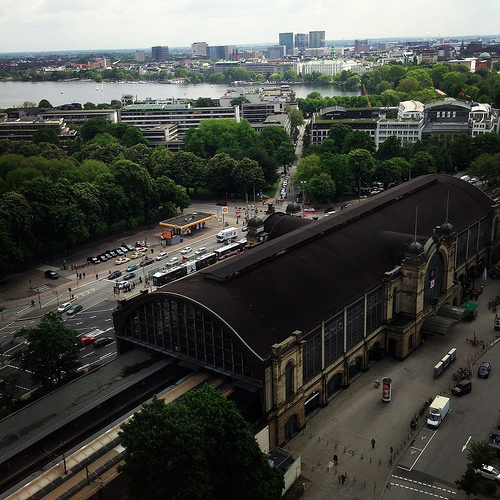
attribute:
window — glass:
[198, 351, 211, 372]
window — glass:
[132, 312, 141, 324]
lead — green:
[133, 167, 135, 170]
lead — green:
[102, 181, 104, 183]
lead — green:
[90, 167, 95, 172]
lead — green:
[220, 162, 222, 165]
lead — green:
[243, 171, 246, 175]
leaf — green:
[109, 125, 115, 131]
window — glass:
[183, 301, 193, 320]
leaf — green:
[102, 167, 112, 173]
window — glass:
[183, 320, 198, 340]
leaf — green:
[85, 166, 93, 173]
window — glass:
[204, 352, 216, 367]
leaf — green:
[132, 167, 137, 187]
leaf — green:
[117, 127, 124, 131]